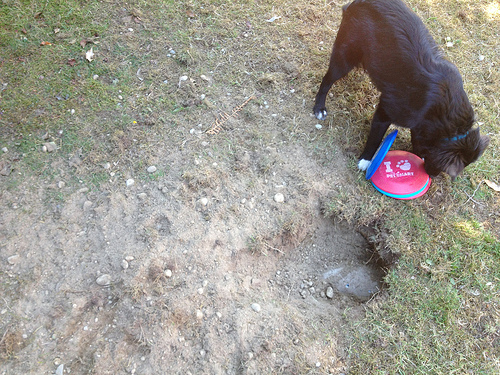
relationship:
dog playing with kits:
[325, 3, 487, 187] [383, 136, 418, 201]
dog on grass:
[325, 3, 487, 187] [6, 14, 42, 46]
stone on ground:
[273, 192, 286, 207] [196, 100, 258, 162]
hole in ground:
[305, 226, 384, 307] [196, 100, 258, 162]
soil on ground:
[238, 45, 265, 77] [196, 100, 258, 162]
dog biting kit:
[325, 3, 487, 187] [383, 136, 418, 201]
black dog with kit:
[382, 45, 415, 76] [383, 136, 418, 201]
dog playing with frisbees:
[325, 3, 487, 187] [383, 136, 418, 201]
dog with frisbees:
[325, 3, 487, 187] [383, 136, 418, 201]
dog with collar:
[325, 3, 487, 187] [445, 128, 467, 142]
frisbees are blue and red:
[383, 136, 418, 201] [389, 160, 413, 192]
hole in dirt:
[305, 226, 384, 307] [98, 206, 145, 267]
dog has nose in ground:
[325, 3, 487, 187] [196, 100, 258, 162]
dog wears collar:
[325, 3, 487, 187] [445, 128, 467, 142]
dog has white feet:
[325, 3, 487, 187] [356, 159, 369, 170]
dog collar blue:
[325, 3, 487, 187] [445, 126, 470, 148]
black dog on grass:
[382, 45, 415, 76] [6, 14, 42, 46]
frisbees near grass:
[287, 4, 385, 198] [6, 14, 42, 46]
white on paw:
[362, 161, 368, 165] [313, 108, 329, 119]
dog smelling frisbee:
[325, 3, 487, 187] [383, 136, 418, 201]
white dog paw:
[362, 161, 368, 165] [313, 108, 329, 119]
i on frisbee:
[383, 163, 396, 173] [383, 136, 418, 201]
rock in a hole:
[322, 285, 334, 299] [305, 226, 384, 307]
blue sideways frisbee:
[445, 126, 470, 148] [372, 137, 403, 175]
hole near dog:
[305, 226, 384, 307] [325, 3, 487, 187]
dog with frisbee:
[325, 3, 487, 187] [372, 137, 403, 175]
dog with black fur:
[325, 3, 487, 187] [355, 21, 378, 48]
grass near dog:
[6, 14, 42, 46] [325, 3, 487, 187]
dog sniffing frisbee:
[325, 3, 487, 187] [372, 137, 403, 175]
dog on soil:
[325, 3, 487, 187] [238, 45, 265, 77]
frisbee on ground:
[372, 137, 403, 175] [196, 100, 258, 162]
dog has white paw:
[325, 3, 487, 187] [313, 108, 329, 119]